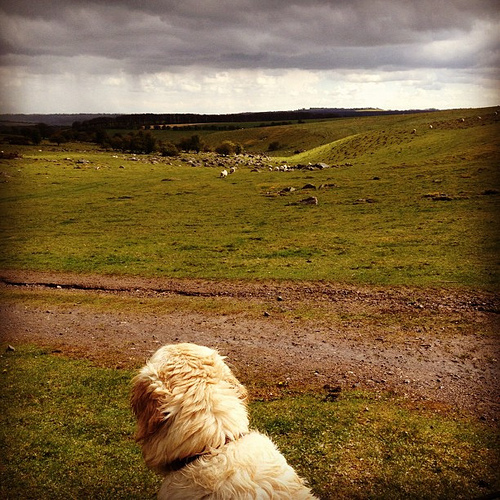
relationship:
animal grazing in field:
[0, 109, 499, 182] [1, 117, 495, 459]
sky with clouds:
[1, 0, 498, 113] [0, 2, 499, 115]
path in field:
[8, 259, 489, 430] [8, 127, 494, 497]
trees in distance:
[4, 109, 196, 159] [21, 112, 461, 195]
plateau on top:
[284, 93, 396, 118] [271, 95, 421, 139]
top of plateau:
[271, 95, 421, 139] [284, 93, 396, 118]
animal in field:
[0, 109, 499, 182] [114, 172, 215, 202]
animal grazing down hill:
[0, 109, 499, 182] [156, 117, 498, 250]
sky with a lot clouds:
[1, 0, 498, 113] [94, 20, 401, 157]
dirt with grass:
[2, 267, 498, 427] [3, 109, 498, 499]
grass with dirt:
[3, 109, 498, 499] [2, 267, 498, 427]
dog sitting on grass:
[128, 341, 319, 499] [9, 367, 122, 492]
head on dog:
[118, 342, 269, 458] [116, 335, 292, 497]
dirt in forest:
[2, 267, 498, 427] [10, 107, 286, 160]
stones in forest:
[259, 177, 350, 219] [10, 107, 286, 160]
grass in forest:
[3, 109, 498, 297] [10, 107, 286, 160]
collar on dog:
[150, 427, 267, 474] [128, 341, 319, 499]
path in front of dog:
[8, 259, 489, 430] [131, 346, 281, 488]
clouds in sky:
[0, 2, 496, 101] [1, 0, 498, 113]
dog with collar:
[128, 341, 319, 499] [159, 425, 261, 475]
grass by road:
[3, 109, 498, 499] [3, 269, 497, 421]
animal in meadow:
[0, 109, 499, 182] [0, 145, 498, 313]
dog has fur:
[128, 341, 319, 499] [135, 342, 307, 498]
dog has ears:
[116, 335, 292, 497] [131, 375, 168, 457]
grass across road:
[3, 109, 498, 499] [3, 269, 497, 421]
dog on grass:
[128, 341, 319, 499] [295, 444, 385, 498]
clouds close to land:
[0, 2, 499, 115] [39, 94, 469, 292]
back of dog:
[157, 430, 315, 498] [138, 331, 269, 459]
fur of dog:
[184, 386, 230, 429] [130, 344, 334, 498]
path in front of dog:
[0, 259, 500, 430] [42, 276, 490, 414]